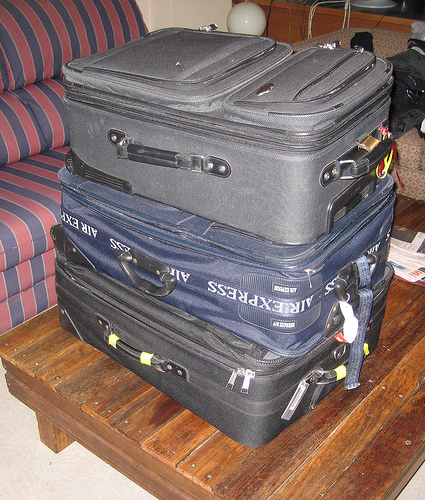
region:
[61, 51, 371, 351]
suitcases stacked on each other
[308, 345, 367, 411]
handle of the suitcase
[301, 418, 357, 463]
table under the bags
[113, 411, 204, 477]
lines on the table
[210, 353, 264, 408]
zipper on the bag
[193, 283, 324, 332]
word on the suitcase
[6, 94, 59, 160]
blue and red lines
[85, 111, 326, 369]
different colored suitcases on top of each other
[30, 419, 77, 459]
leg of the table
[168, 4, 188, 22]
wall in the background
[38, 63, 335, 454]
three suitcases stacked on table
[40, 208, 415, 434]
black suitcase on table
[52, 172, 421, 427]
blue suitcase on top of black suitcase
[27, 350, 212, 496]
finishing nails on wood table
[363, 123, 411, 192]
red and yellow tag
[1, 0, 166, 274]
red, blue, and white couch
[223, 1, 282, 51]
white round light globe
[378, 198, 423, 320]
newspaper laying on table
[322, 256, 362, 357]
white tag on handle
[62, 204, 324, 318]
white letters on blue suitcase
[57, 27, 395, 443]
A stack of suitcases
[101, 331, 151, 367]
Yellow tape on the bags handle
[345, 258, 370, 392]
a blue strap hanging from the luggage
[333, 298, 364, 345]
The white underside of a red tag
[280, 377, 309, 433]
The long metal grip for the zipper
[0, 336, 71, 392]
Rivets in the wooden table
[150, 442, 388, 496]
The wooden coffee table under the bags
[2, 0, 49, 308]
The blue and pink striped couch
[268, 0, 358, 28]
Chords hanging from the desk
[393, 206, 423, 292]
A folded magazine on top of the coffee table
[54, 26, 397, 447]
a stack of suitcases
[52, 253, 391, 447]
a black suitcase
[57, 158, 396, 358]
a dark blue suitcase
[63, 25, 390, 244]
a grey suitcase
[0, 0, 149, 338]
a red and blue striped sofa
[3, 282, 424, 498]
a dark wooden table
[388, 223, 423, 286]
paper media on a wooden table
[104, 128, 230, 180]
handle on a grey piece of luggage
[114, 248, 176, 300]
a black plastic handle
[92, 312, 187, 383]
a handle with yellow tape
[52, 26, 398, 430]
three suitcases stacked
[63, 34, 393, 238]
the gray suitcase on top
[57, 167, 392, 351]
the blue suitcase in the middle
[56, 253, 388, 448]
the black suitcase on the bottom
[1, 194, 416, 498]
an old wooden coffee table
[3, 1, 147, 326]
a blue and red stripped couch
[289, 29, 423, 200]
a brown patterned chair with black bags on it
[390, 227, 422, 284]
a newspaper on the coffee table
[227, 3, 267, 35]
a white ball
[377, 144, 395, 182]
yellow and red yarn on the gray suitcase